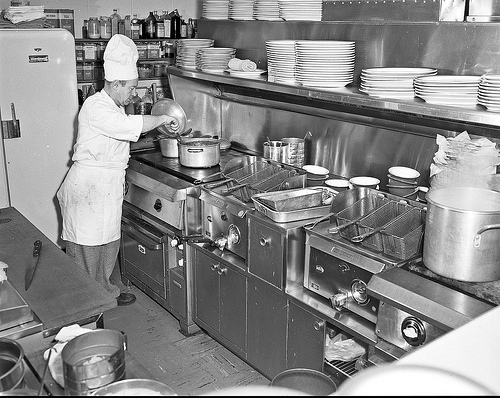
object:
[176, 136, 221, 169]
pot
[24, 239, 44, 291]
knife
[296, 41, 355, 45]
plates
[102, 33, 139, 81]
hat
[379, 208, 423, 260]
basket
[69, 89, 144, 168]
shirt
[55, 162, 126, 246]
apron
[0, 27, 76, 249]
fridge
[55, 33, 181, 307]
chef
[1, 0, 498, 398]
kitchen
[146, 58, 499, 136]
shelf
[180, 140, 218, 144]
soup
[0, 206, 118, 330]
cutting board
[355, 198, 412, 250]
fryer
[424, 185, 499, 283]
pot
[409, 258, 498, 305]
counter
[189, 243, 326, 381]
cabinets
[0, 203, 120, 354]
table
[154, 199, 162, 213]
dial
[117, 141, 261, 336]
stove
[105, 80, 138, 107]
light skin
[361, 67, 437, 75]
plates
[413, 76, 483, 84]
plates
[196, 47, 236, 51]
plates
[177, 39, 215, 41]
plates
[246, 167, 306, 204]
fryer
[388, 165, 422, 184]
soup bowl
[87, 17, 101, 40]
spice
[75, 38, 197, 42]
shelf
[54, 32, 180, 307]
man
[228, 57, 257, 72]
towl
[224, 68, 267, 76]
plate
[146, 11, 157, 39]
bottle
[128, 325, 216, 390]
floor